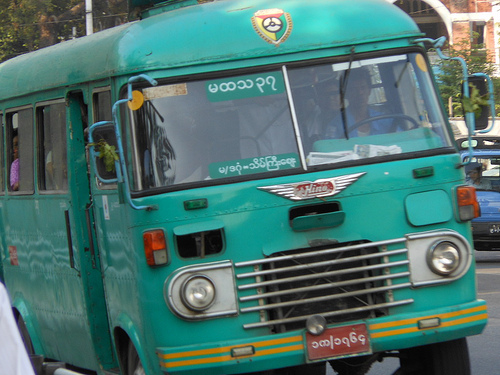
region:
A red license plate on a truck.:
[301, 319, 369, 366]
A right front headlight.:
[164, 257, 236, 322]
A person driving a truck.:
[318, 71, 409, 136]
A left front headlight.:
[424, 236, 466, 281]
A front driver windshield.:
[281, 60, 462, 169]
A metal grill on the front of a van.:
[224, 228, 419, 333]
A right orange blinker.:
[139, 222, 176, 274]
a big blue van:
[6, 5, 483, 370]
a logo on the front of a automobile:
[246, 5, 300, 50]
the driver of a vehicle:
[322, 58, 422, 155]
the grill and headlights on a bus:
[139, 183, 487, 317]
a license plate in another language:
[300, 320, 378, 364]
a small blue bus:
[3, 3, 490, 374]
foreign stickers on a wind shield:
[202, 71, 309, 179]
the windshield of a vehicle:
[116, 40, 470, 197]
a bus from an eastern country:
[2, 0, 482, 367]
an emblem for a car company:
[247, 164, 375, 209]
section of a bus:
[34, 270, 219, 373]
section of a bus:
[234, 240, 453, 372]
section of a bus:
[84, 135, 321, 357]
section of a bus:
[0, 149, 177, 373]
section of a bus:
[344, 95, 489, 373]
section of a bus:
[32, 62, 247, 283]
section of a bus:
[261, 85, 497, 297]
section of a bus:
[165, 139, 439, 373]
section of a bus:
[130, 225, 277, 370]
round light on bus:
[181, 279, 225, 319]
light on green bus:
[431, 231, 463, 291]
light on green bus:
[302, 311, 336, 344]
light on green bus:
[136, 229, 174, 269]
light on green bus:
[452, 179, 486, 231]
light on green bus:
[178, 175, 217, 220]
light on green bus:
[411, 158, 439, 188]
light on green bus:
[228, 341, 266, 368]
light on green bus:
[411, 306, 464, 341]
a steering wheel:
[351, 117, 384, 131]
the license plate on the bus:
[302, 330, 377, 358]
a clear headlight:
[185, 273, 219, 307]